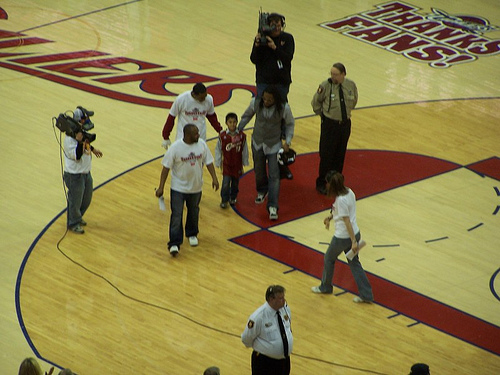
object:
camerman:
[249, 5, 296, 102]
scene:
[0, 0, 499, 374]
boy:
[212, 110, 251, 210]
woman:
[310, 168, 378, 302]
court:
[0, 0, 500, 374]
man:
[155, 121, 221, 256]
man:
[159, 82, 226, 152]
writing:
[316, 0, 499, 70]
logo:
[0, 6, 259, 112]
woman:
[11, 353, 61, 375]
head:
[17, 357, 43, 375]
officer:
[311, 61, 359, 195]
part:
[95, 17, 231, 51]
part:
[260, 19, 268, 32]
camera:
[256, 6, 276, 46]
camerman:
[50, 104, 105, 238]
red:
[230, 152, 244, 175]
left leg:
[311, 236, 345, 296]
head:
[183, 121, 202, 145]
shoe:
[169, 244, 182, 257]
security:
[239, 283, 299, 375]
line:
[262, 161, 468, 232]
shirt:
[330, 188, 363, 240]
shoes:
[185, 233, 200, 248]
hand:
[264, 35, 279, 53]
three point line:
[0, 0, 144, 50]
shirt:
[310, 78, 359, 122]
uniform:
[309, 79, 356, 182]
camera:
[54, 105, 97, 145]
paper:
[153, 185, 167, 212]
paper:
[343, 241, 368, 263]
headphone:
[268, 286, 290, 311]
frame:
[320, 11, 373, 39]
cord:
[53, 133, 387, 375]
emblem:
[316, 84, 327, 97]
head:
[264, 280, 289, 310]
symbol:
[182, 106, 207, 122]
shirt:
[168, 92, 214, 147]